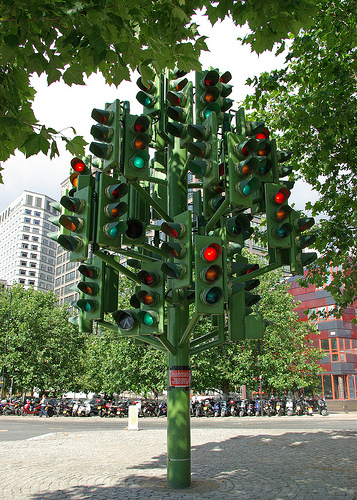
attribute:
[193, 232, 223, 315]
light — for traffic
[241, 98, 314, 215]
traffic signal —  light,  red , for  traffic 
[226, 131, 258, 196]
traffic light — for traffic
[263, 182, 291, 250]
traffic light — for traffic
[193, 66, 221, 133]
light — for  traffic ,  red,  signal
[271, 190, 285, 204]
signal light —  signal,  red,  for traffic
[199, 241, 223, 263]
light — red ,  for traffic,  signal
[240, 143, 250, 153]
light — for traffic,  red ,  signal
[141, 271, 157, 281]
light —  red,  signal , for traffic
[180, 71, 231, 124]
light —  signal,  red, for traffic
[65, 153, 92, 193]
traffic signal —  for traffic,  light,  red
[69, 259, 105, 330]
traffic light — for traffic